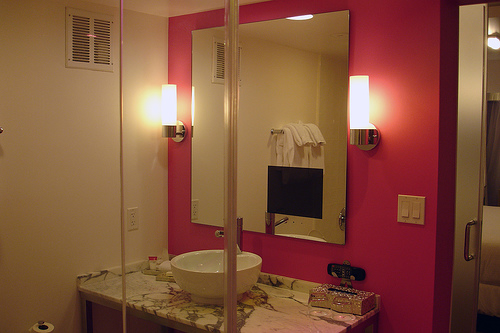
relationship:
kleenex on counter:
[310, 281, 375, 316] [76, 255, 381, 332]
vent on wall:
[64, 6, 118, 74] [1, 1, 168, 332]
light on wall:
[348, 74, 381, 152] [167, 2, 459, 331]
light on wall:
[160, 84, 187, 143] [167, 2, 459, 331]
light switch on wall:
[397, 193, 426, 225] [167, 2, 459, 331]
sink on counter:
[170, 247, 263, 305] [76, 255, 381, 332]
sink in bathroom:
[170, 247, 263, 305] [1, 1, 487, 332]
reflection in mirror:
[265, 116, 346, 246] [190, 9, 350, 245]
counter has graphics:
[76, 255, 381, 332] [127, 276, 270, 332]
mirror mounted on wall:
[190, 9, 350, 245] [167, 2, 459, 331]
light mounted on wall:
[160, 84, 187, 143] [167, 2, 459, 331]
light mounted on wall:
[348, 74, 381, 152] [167, 2, 459, 331]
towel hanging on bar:
[275, 127, 295, 167] [270, 127, 285, 136]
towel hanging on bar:
[303, 122, 326, 168] [270, 127, 285, 136]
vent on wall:
[64, 6, 118, 74] [167, 2, 459, 331]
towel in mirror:
[275, 127, 295, 167] [190, 9, 350, 245]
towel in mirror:
[287, 123, 312, 169] [190, 9, 350, 245]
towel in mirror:
[303, 122, 326, 168] [190, 9, 350, 245]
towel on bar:
[275, 127, 295, 167] [270, 127, 285, 136]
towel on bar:
[287, 123, 312, 169] [270, 127, 285, 136]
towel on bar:
[303, 122, 326, 168] [270, 127, 285, 136]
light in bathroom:
[160, 84, 187, 143] [1, 1, 487, 332]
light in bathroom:
[348, 74, 381, 152] [1, 1, 487, 332]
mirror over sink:
[190, 9, 350, 245] [170, 247, 263, 305]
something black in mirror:
[266, 164, 323, 219] [189, 24, 344, 244]